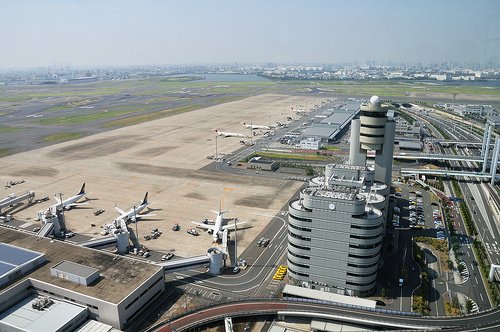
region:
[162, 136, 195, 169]
part of a runway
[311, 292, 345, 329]
part of a road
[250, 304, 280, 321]
edge of a road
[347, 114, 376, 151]
part of a building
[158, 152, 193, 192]
part of a runway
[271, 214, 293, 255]
edge of a building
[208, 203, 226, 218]
part of a plane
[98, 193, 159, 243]
plane at the airport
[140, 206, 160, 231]
wing of the plane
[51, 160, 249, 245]
three planes next to each other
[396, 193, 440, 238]
many cars parked in parking lot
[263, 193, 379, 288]
building next to planes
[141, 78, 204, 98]
grass on the ground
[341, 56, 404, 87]
buildings in the background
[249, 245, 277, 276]
white lines on the ground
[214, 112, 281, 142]
planes in the distance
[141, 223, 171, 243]
cars next to plane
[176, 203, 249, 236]
airplane parked on runway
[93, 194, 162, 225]
airplane parked on runway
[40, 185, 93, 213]
airplane parked on runway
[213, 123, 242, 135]
airplane parked on runway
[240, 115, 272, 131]
airplane parked on runway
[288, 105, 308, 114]
airplane parked on runway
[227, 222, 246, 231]
wing on side of plane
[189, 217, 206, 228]
wing on side of plane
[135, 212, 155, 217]
wing on side of plane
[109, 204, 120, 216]
wing on side of plane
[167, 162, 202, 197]
part of a runway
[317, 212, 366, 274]
part of a tower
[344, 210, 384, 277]
edge of a building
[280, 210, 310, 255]
edge of a building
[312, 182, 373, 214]
top of a building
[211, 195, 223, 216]
part of a plane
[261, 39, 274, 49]
part of the sky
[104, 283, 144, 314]
edge of a building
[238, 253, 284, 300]
White lines marking the road.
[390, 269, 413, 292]
White truck driving on road.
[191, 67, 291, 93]
Body of water in distance.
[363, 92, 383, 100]
White object on top of building.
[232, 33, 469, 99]
Many buildings in the distance.